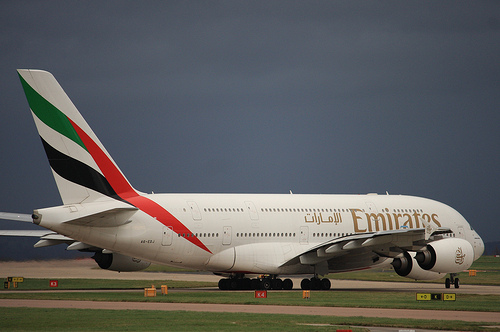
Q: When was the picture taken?
A: Daytime.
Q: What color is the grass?
A: Green.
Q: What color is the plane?
A: White.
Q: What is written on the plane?
A: Emirates.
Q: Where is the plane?
A: On the runway.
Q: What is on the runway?
A: The plane.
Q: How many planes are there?
A: One.